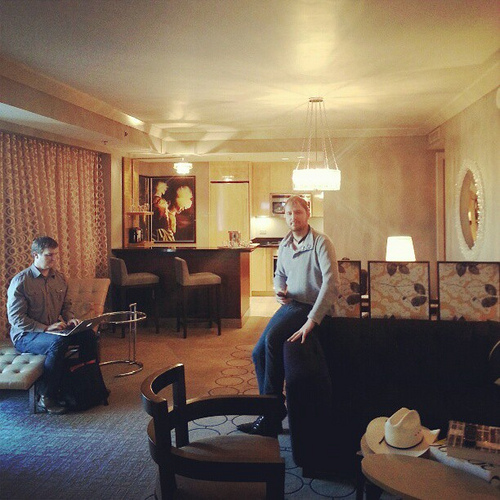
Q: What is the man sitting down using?
A: Laptop.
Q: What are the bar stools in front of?
A: The bar.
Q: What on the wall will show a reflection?
A: The mirror.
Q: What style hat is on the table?
A: Cowboy hat.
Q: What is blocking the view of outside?
A: The curtains.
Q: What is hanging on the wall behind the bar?
A: Framed picture.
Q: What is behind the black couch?
A: Room divider.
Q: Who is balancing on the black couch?
A: The man holding something.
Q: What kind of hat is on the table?
A: A cowboy hat.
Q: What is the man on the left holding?
A: A laptop.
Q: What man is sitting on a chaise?
A: The man on the left.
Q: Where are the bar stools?
A: At the bar.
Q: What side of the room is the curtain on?
A: The left side.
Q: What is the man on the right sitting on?
A: The arm of the couch.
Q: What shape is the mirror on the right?
A: Circular.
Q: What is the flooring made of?
A: Carpet.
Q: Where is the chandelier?
A: Behind the man on the couch.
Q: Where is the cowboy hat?
A: On the side table.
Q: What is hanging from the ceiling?
A: A light fixture.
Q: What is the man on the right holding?
A: A phone.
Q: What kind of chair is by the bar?
A: Barstools.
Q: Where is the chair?
A: Next to the couch.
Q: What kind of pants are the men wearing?
A: Jeans.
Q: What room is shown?
A: Den.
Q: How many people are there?
A: Two.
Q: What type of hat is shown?
A: Cowboy.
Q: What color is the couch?
A: Black.